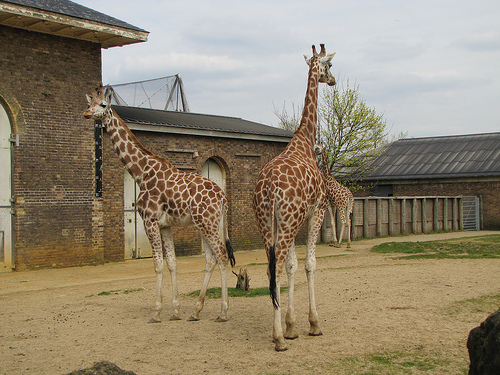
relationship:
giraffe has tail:
[57, 69, 246, 334] [203, 223, 246, 286]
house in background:
[163, 105, 291, 211] [46, 42, 442, 311]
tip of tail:
[229, 254, 254, 272] [203, 223, 246, 286]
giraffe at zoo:
[57, 69, 246, 334] [46, 42, 442, 311]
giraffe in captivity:
[57, 69, 246, 334] [46, 42, 442, 311]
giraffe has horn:
[57, 69, 246, 334] [80, 84, 111, 105]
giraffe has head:
[57, 69, 246, 334] [73, 73, 127, 135]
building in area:
[110, 84, 297, 248] [46, 42, 442, 311]